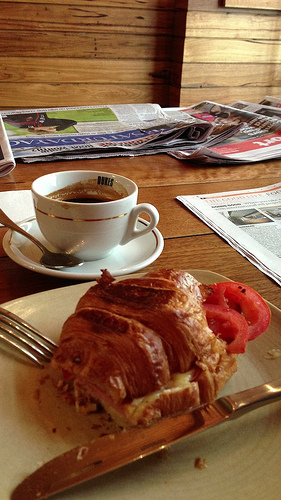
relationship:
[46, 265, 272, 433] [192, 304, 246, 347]
food with tomato slice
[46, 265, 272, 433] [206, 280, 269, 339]
food with tomato slice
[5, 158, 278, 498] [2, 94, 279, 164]
table under newspaper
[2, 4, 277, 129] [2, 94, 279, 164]
wall next to newspaper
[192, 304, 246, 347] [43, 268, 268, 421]
tomato slice on sandwich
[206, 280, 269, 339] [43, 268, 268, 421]
tomato slice on sandwich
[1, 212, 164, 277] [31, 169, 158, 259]
saucer matching cup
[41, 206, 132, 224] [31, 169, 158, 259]
stripe around cup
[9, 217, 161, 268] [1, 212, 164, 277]
stripe around saucer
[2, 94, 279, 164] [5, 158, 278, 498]
newspaper on table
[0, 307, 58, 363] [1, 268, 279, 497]
fork on plate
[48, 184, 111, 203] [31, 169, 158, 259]
coffee in cup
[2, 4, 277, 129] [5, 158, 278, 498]
wall behind table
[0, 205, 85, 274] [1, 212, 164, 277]
spoon on saucer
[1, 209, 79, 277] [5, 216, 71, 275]
spoon on plate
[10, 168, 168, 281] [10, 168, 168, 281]
cup on saucer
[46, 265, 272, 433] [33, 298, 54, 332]
food on plate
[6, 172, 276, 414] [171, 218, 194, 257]
tea on table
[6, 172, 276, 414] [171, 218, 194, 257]
food on table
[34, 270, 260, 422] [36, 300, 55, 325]
crossaint sits on plate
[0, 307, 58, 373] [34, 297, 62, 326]
fork lays on plate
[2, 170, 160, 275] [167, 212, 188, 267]
cup sits on table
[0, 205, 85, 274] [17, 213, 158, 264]
spoon on saucer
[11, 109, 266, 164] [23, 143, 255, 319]
newpapers on table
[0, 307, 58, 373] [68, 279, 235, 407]
fork next to sandwich